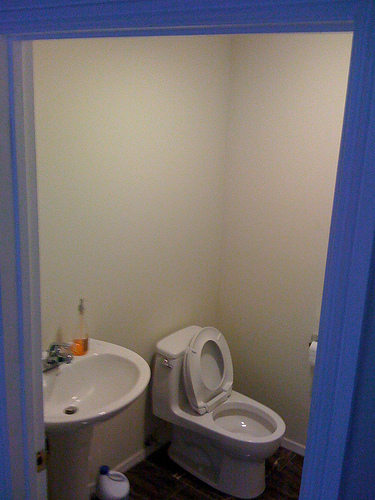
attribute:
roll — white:
[305, 345, 334, 365]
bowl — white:
[195, 400, 258, 444]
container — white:
[103, 457, 135, 497]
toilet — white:
[182, 291, 275, 430]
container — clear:
[53, 297, 108, 351]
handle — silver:
[47, 334, 81, 359]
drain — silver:
[54, 400, 80, 408]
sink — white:
[24, 332, 146, 412]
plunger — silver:
[161, 356, 190, 389]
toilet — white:
[147, 324, 284, 441]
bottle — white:
[95, 465, 162, 495]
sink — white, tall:
[42, 301, 156, 451]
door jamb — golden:
[33, 441, 52, 475]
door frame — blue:
[0, 2, 371, 496]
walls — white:
[214, 32, 355, 458]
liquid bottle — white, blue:
[90, 461, 132, 498]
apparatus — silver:
[156, 347, 175, 373]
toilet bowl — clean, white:
[197, 396, 285, 495]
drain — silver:
[63, 398, 83, 418]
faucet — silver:
[39, 342, 75, 369]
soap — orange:
[73, 333, 92, 355]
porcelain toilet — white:
[155, 320, 285, 496]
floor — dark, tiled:
[119, 431, 307, 497]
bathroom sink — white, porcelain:
[39, 335, 148, 498]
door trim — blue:
[0, 4, 369, 496]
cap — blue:
[97, 462, 110, 476]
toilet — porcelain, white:
[151, 320, 285, 496]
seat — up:
[187, 323, 236, 415]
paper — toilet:
[307, 332, 321, 367]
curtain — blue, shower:
[296, 8, 362, 498]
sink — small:
[33, 334, 154, 496]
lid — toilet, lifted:
[179, 327, 235, 414]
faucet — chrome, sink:
[42, 341, 71, 370]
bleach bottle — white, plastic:
[88, 459, 133, 498]